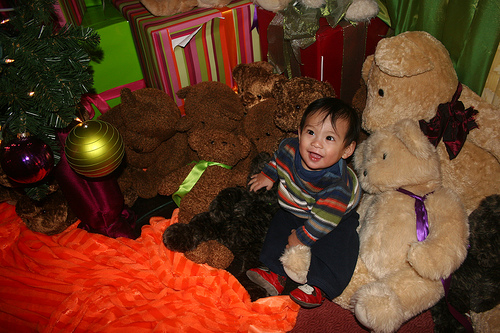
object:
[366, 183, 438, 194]
neck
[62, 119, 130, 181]
ornament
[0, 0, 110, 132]
tree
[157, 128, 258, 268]
bear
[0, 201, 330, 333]
blanket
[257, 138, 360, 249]
sweater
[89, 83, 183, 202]
bears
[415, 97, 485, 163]
bow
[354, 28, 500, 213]
teddy bear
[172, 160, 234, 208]
ribbon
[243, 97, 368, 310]
baby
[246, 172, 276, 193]
right hand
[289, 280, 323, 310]
shoe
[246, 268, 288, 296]
red shoes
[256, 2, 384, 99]
box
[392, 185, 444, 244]
ribbon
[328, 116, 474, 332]
bear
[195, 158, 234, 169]
neck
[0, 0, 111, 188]
decorations